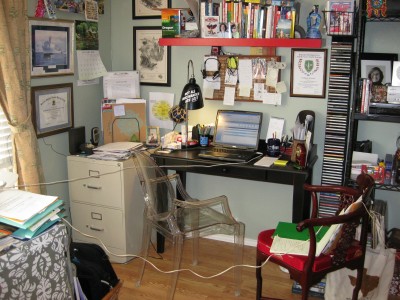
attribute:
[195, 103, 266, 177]
laptop — on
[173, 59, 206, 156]
light — on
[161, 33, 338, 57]
shelf — red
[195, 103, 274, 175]
laptop — black